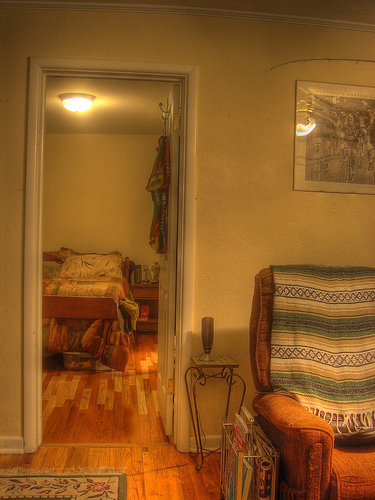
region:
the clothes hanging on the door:
[144, 134, 169, 253]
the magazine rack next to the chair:
[219, 404, 279, 498]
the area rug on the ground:
[0, 467, 126, 498]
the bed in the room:
[42, 246, 128, 372]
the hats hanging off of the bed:
[115, 296, 139, 334]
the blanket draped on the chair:
[269, 264, 374, 433]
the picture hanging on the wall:
[292, 79, 373, 193]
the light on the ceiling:
[56, 93, 95, 112]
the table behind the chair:
[184, 355, 245, 470]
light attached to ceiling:
[49, 87, 101, 126]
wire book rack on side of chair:
[207, 405, 284, 495]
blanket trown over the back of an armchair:
[268, 258, 373, 411]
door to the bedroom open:
[18, 53, 203, 447]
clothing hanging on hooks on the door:
[131, 96, 182, 253]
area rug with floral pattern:
[3, 455, 132, 496]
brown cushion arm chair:
[241, 248, 373, 487]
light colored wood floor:
[14, 308, 198, 496]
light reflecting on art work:
[269, 104, 325, 153]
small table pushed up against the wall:
[179, 350, 258, 473]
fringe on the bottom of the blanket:
[306, 403, 373, 439]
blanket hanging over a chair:
[256, 254, 374, 443]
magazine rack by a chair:
[210, 407, 284, 498]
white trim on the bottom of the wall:
[0, 434, 27, 457]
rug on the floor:
[1, 463, 130, 499]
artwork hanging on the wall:
[282, 74, 374, 197]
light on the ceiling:
[61, 93, 97, 114]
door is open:
[143, 80, 193, 438]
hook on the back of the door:
[155, 96, 174, 125]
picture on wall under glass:
[292, 78, 373, 192]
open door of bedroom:
[27, 56, 197, 455]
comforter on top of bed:
[42, 249, 137, 371]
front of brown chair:
[251, 264, 373, 494]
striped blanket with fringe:
[270, 265, 369, 433]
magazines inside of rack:
[222, 405, 275, 498]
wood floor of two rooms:
[1, 329, 218, 498]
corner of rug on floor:
[1, 466, 127, 497]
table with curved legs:
[184, 354, 245, 471]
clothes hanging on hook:
[146, 100, 171, 255]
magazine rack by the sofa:
[202, 417, 275, 489]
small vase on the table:
[200, 314, 220, 361]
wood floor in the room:
[80, 389, 143, 429]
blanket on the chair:
[265, 268, 358, 443]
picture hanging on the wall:
[284, 67, 369, 193]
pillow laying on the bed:
[57, 248, 120, 279]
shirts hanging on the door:
[145, 133, 169, 246]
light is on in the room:
[54, 90, 97, 115]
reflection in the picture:
[294, 90, 317, 149]